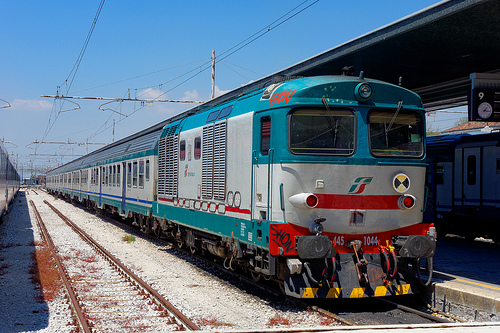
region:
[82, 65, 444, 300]
commuter train on tracks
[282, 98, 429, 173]
front windows on train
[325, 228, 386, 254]
numbers on front of train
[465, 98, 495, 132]
clock over train platform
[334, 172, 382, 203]
logo on front of train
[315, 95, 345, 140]
windshield wiper on train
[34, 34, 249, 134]
wires over train track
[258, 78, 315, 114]
red design on blue roof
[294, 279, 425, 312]
yellow lines on front of train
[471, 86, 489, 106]
number above clock face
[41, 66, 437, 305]
blue and grey train with many carriages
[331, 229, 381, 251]
identifying numbers on the front of a train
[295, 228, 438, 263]
black buffers on the front of a train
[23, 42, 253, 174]
power cables crossing the sky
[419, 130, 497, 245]
a second train is at the station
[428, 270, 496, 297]
yellow line painted on a railway platform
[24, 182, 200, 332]
straight parallel metal railway tracks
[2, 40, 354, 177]
blue sky with a few fluffy white clouds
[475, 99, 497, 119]
a clock above a railway platform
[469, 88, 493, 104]
the platform number is 9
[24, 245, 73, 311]
Plant growth at the tracks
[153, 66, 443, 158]
An engine with a blue top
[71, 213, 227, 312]
Gravel covers the ground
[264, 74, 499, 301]
Two trains sitting on parallel tracks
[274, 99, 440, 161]
The front windows of the engine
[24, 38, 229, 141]
Wires run overhead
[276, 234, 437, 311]
A guard with yellow stripes on the front of the engine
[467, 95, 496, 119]
A clock for passengers to check the time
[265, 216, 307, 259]
Graffiti on the front of the engine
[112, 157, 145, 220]
A blue door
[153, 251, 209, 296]
there is gravel between the tracks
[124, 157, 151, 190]
the train has windows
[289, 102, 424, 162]
the train has a windshield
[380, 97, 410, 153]
the windshield has a wiper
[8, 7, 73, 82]
the sky is blue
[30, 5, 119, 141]
the wires are long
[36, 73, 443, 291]
the train on tracks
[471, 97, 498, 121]
the clock is at 1:15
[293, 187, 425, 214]
the train has headlights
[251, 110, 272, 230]
the train has a door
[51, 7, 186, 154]
suspended power lines for trains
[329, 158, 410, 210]
a red and blue logo on a train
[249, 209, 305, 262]
graffiti on a train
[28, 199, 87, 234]
train tracks with white gravel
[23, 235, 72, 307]
grass beside a train track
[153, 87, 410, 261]
teal colored train locomotive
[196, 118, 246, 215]
engine intake vents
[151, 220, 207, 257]
train wheels on a track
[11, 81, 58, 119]
a cloud in the sky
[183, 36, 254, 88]
wiring on a pole